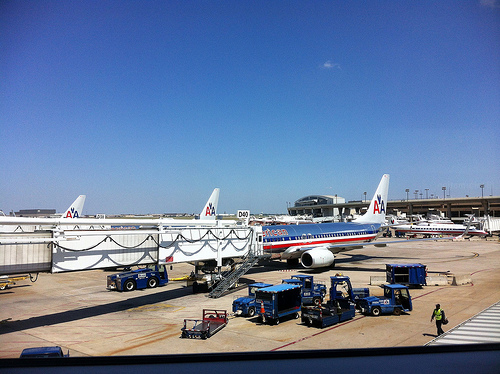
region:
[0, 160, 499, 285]
Airplanes are sitting on the runway.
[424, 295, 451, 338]
A person is walking on the runway.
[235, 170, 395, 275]
An airplane's colors are blue, white, and red.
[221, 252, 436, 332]
A group of service vehicles are parked near an airplane.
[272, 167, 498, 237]
A building is in the background.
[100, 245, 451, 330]
The service vehicles are blue.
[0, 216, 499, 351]
The runway is a tan color.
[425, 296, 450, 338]
A person is wearing a green vest.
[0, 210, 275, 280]
An extension is leading to one of the aircraft.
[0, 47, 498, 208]
The sky is a very blue color.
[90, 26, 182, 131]
clear blue skies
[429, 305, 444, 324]
a man in green jacket on runway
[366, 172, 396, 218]
back of the airplane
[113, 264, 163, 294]
a blue machine on the runway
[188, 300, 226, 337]
a red machine on the runway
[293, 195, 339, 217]
airport terminal in the backgorund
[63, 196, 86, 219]
the top of another plane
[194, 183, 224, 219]
it is the top of an airplane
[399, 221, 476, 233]
a white airplane in the background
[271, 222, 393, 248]
a silver and blue airplane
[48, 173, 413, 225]
Three airlines belong to American Airlines.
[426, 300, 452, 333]
The man is wearing a safety vest.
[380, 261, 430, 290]
The luggage cart has a curtain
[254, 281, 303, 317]
The luggage cart is empty.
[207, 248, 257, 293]
There is a ladder leading to the hallway into the plane.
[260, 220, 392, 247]
The plane's silver paint sparkles in the sunshine.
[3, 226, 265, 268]
Passenger walkway from the gate/waiting area to the plane.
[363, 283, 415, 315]
Small transport truck for employees who are working on the plane.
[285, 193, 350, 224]
Another terminal on the other side of the airport.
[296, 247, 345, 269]
One engine on the large plane.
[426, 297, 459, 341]
man walking on cement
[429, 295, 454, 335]
man in yellow vest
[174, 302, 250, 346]
cart on a tarmac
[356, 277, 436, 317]
blue vehicle on tarmac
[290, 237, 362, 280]
white and silver plane engine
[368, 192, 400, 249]
AA on a plane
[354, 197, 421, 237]
white plane tail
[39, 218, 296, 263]
White ramp to airplane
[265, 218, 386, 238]
windows on the side of a plane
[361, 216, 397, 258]
exit door on the back of a plane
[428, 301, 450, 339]
an airport worker walking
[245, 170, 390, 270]
an airplane at the gate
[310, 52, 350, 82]
a single cloud in the sky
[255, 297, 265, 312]
an orange and white traffic cone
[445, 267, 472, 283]
a white k-rail barricade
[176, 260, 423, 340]
many airport baggage trucks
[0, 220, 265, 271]
a long passenger ramp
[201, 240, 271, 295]
staircase for airport workers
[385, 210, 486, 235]
an airplane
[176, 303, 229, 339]
an empty baggage cart